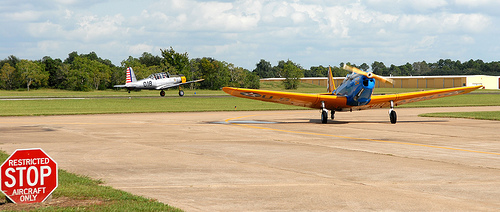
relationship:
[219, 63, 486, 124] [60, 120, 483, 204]
plane on tarmac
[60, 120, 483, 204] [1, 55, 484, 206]
tarmac at airport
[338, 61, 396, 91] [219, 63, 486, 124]
propellor in front of plane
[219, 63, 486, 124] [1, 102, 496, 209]
plane on tarmac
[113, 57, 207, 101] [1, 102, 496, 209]
plane on tarmac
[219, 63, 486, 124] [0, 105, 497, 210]
plane taxiing on runway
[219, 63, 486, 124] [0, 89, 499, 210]
plane on ground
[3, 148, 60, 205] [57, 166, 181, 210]
board in grass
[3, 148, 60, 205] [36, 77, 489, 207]
board in ground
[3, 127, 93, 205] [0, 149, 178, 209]
board in earth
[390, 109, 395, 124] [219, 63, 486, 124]
wheel of plane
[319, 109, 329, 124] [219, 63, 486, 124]
wheel of plane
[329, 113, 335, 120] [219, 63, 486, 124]
wheel of plane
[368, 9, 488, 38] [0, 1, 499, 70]
cloud fills sky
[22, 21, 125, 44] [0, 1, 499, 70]
cloud fills sky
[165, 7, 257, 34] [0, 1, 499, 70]
cloud fills sky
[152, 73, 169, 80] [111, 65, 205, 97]
canopy of plane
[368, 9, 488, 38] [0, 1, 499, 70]
cloud in sky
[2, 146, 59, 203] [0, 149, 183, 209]
sign on ground